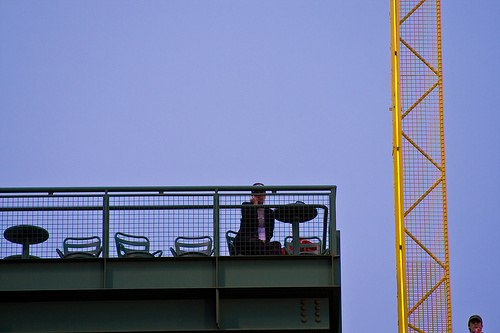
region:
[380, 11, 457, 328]
The metal tower is yellow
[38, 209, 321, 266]
Seats behind the fence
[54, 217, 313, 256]
The seats are green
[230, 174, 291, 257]
The person is sitting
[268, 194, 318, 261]
The table is green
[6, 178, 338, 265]
The railing is green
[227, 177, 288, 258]
The person is talking on their phone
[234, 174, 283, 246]
The person is sitting next to the table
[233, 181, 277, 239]
The person is wearing a black sweater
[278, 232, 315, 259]
A red bag on a chair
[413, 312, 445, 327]
yellow mesh on wire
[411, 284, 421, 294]
yellow mesh on wire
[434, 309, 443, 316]
yellow mesh on wire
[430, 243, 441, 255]
yellow mesh on wire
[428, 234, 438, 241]
yellow mesh on wire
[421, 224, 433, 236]
yellow mesh on wire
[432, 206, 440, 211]
yellow mesh on wire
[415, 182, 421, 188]
yellow mesh on wire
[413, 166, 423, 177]
yellow mesh on wire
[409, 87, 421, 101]
yellow mesh on wire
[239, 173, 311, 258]
person eating at table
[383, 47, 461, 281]
yellow post at baseball field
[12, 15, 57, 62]
whiet clouds against blue sky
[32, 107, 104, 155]
whiet clouds against blue sky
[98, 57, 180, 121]
whiet clouds against blue sky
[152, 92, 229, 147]
whiet clouds against blue sky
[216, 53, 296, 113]
whiet clouds against blue sky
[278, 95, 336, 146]
whiet clouds against blue sky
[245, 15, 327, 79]
whiet clouds against blue sky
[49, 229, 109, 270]
green chair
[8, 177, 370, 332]
an upper deck at a baseball stadium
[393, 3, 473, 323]
a foul ball marker on a baseball field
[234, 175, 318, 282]
a man sitting talking on his cell phone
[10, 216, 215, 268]
empty seats on an outdoor patio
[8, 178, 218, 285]
green tables and chairs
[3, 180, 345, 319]
a green fence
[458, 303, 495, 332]
a man wearing a baseball cap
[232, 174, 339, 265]
a person sitting at a table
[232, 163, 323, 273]
a person sitting alone at a table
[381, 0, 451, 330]
a tall yellow structure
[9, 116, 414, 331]
a person sitting on a platform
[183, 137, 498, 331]
these people are high up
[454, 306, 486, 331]
you can barely see this person's head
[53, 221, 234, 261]
chairs on the platform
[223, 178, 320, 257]
this person is talking to someone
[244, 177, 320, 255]
this person is sitting next to a table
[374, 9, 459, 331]
this object is yellow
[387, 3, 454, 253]
this object is long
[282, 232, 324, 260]
something red is in this scene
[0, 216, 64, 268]
this table is empty